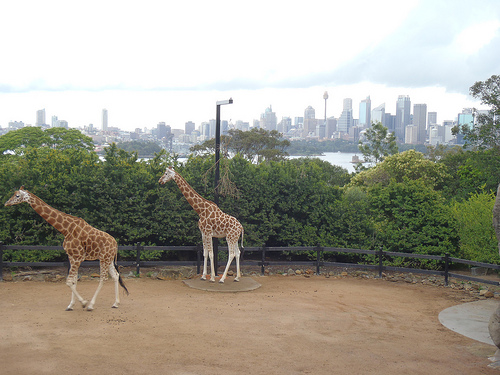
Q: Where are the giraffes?
A: In the park.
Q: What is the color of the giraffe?
A: Brown.